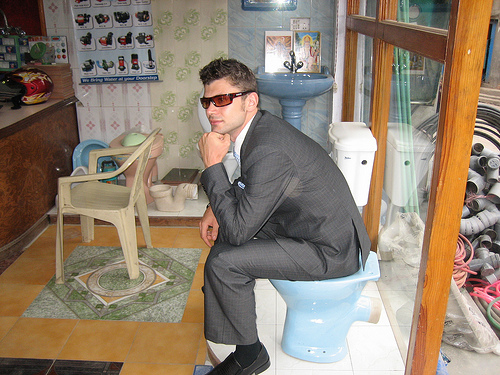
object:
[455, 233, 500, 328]
cords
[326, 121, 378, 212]
back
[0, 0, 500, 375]
toilet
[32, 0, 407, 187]
wall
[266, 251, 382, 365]
blue toilet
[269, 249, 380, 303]
toilet seat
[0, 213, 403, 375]
ground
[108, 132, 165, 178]
toilet seat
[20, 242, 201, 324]
tile inlay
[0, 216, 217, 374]
floor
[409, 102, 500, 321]
plumbing pipes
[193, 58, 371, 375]
man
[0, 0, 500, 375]
bathroom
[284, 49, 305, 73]
faucet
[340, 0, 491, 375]
window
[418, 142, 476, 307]
trim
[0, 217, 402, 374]
tile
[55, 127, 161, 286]
chair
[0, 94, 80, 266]
counter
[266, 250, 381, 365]
toliet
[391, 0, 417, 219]
curtain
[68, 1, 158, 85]
poster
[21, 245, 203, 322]
design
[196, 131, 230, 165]
hand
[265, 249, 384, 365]
seat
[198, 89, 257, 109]
glasses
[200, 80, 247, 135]
face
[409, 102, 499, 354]
amount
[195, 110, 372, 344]
suit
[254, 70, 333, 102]
sink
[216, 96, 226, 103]
eyes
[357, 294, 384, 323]
part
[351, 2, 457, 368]
glass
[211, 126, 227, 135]
chin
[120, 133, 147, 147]
ball